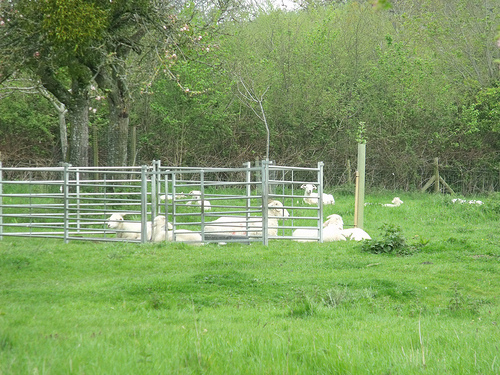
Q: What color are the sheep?
A: White.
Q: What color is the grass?
A: Green.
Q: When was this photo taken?
A: During the day.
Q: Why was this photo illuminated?
A: Sunlight.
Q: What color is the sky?
A: Gray.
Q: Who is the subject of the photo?
A: The sheep.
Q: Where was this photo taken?
A: In a field.